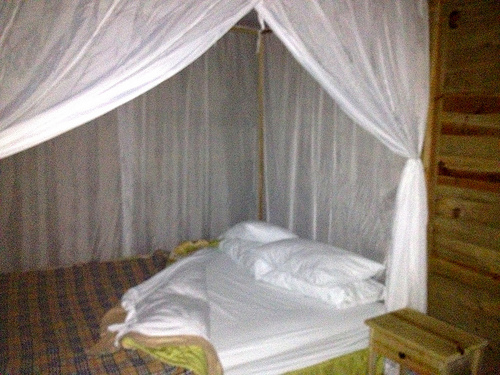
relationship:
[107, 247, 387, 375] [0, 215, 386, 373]
sheet on bed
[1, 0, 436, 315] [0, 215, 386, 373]
curtains over bed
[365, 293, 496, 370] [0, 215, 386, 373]
nightstand next bed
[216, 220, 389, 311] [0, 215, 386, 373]
pillows on bed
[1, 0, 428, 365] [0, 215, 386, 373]
net above bed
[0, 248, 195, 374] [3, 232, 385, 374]
blanket on bed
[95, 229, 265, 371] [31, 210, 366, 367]
blanket over bed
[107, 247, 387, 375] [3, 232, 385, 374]
sheet on bed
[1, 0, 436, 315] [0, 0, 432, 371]
curtains around bed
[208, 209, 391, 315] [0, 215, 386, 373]
pillows on bed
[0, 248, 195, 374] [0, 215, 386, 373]
blanket on bed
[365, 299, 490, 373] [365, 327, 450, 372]
table has drawer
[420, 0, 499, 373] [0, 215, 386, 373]
wall next bed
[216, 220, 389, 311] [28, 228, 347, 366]
pillows on bed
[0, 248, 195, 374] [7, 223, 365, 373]
blanket on bed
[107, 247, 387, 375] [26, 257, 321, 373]
sheet on bed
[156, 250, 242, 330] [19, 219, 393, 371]
sheet on bed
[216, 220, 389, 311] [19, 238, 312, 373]
pillows on bed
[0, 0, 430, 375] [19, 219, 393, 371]
curtains on bed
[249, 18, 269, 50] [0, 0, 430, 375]
tie on curtains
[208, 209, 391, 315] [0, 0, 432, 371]
pillows on bed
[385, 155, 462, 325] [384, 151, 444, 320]
cloth has buttom part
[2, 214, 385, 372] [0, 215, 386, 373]
combo on bed